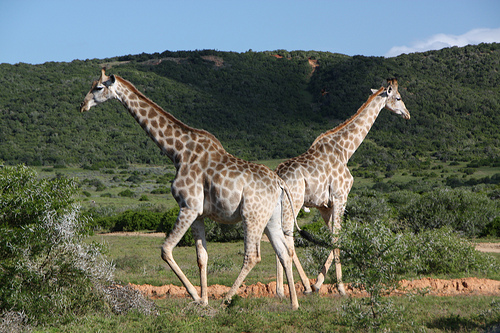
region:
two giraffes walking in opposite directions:
[77, 62, 433, 289]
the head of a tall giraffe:
[60, 70, 122, 112]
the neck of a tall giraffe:
[118, 76, 203, 173]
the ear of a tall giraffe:
[95, 63, 120, 88]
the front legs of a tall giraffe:
[165, 202, 216, 294]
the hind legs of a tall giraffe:
[237, 209, 289, 304]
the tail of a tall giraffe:
[276, 170, 320, 251]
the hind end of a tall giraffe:
[232, 162, 297, 236]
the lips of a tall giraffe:
[79, 98, 89, 115]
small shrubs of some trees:
[10, 182, 123, 304]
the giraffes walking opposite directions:
[70, 46, 418, 316]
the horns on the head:
[96, 65, 108, 80]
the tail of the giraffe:
[281, 180, 336, 251]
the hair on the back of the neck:
[310, 86, 385, 152]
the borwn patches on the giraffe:
[179, 164, 268, 211]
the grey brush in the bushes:
[45, 206, 147, 325]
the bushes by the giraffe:
[0, 160, 147, 319]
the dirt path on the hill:
[302, 51, 330, 101]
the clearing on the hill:
[104, 45, 239, 76]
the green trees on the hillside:
[409, 44, 494, 161]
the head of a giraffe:
[372, 74, 411, 118]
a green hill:
[161, 45, 314, 115]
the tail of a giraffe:
[283, 181, 305, 235]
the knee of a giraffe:
[161, 240, 175, 263]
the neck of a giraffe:
[123, 88, 178, 145]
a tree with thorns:
[356, 215, 413, 325]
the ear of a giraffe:
[105, 75, 117, 87]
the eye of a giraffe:
[96, 84, 103, 91]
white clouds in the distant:
[416, 32, 470, 44]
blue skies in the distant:
[36, 8, 246, 43]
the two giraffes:
[79, 75, 402, 311]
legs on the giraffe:
[157, 228, 215, 305]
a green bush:
[337, 222, 397, 305]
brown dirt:
[146, 288, 180, 300]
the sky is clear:
[214, 15, 311, 42]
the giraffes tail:
[281, 185, 300, 232]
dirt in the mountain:
[206, 50, 226, 69]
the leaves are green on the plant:
[403, 231, 466, 262]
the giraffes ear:
[385, 86, 395, 96]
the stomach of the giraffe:
[211, 198, 246, 218]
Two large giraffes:
[74, 68, 413, 313]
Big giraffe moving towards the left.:
[76, 67, 345, 314]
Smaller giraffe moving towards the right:
[274, 75, 414, 300]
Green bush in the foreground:
[1, 161, 148, 331]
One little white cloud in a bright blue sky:
[1, 1, 498, 61]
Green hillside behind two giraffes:
[1, 40, 498, 332]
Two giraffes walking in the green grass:
[31, 67, 498, 332]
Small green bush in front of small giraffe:
[296, 216, 476, 332]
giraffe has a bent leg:
[77, 65, 334, 313]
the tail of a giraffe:
[281, 182, 338, 251]